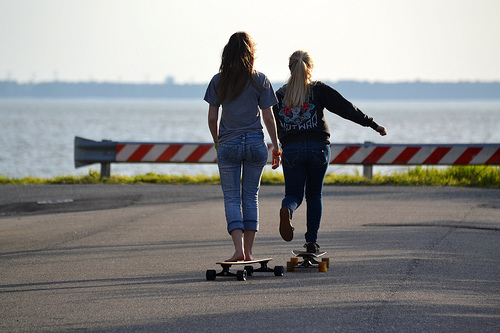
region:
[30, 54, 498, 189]
a body of water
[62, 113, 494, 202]
a traffic guard rail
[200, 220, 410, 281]
two skateboards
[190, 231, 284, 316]
a skateboard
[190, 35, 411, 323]
two women skateboarding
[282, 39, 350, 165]
a woman wearing a pony tail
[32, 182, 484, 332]
black tard road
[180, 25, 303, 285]
a woman wearing jeans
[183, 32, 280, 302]
a woman skateboarding with no shoes on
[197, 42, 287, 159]
a woman with brown hair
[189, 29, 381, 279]
backs of two skateboarders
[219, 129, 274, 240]
back of blue jeans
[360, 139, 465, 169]
red and white stripes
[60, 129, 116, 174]
end of guard rail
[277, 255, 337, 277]
four wheels under skateboard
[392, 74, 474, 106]
land on horizon beyond water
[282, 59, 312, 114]
blonde ponytail on head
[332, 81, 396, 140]
extended arm of skateboarder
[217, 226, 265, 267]
bare feet of skateboarder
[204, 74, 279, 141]
short sleeved tee shirt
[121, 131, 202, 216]
red lines are visible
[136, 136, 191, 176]
red lines are visible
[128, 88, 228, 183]
red lines are visible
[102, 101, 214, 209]
red lines are visible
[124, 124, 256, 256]
red lines are visible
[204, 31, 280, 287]
woman standing on a skateboard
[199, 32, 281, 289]
woman with long red hair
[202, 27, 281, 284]
girl standing on a skateboard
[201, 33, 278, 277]
woman with jeans rolled up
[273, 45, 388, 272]
blond woman pushing off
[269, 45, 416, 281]
girl with blond hair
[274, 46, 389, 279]
blond girl pushing off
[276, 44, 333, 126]
hair in a pony tail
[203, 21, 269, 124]
hair in a huge pony tail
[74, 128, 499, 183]
barrier by the water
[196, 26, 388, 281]
two women on skateboards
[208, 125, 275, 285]
woman on left in carpi-length jeans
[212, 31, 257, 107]
woman on left with brown hair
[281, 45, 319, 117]
woman on right with blond ponytail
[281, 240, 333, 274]
black skateboard with yellow wheels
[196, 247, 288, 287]
wooden skateboard with black wheels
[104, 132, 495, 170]
orange and white diagonal stripes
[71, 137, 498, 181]
orange and white-covered railing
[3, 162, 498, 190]
grass area behind railing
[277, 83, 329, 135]
black shirt with woman's face on back